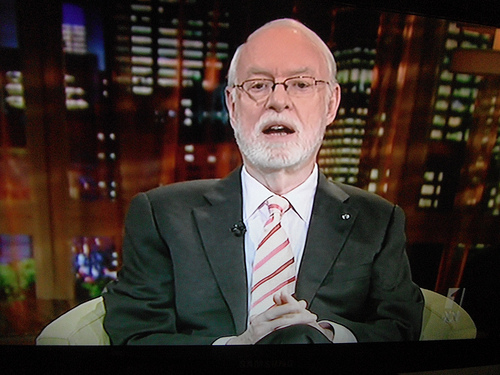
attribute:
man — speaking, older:
[103, 17, 424, 345]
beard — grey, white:
[229, 115, 325, 169]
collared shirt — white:
[239, 163, 318, 330]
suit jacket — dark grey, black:
[100, 163, 424, 344]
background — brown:
[1, 1, 497, 343]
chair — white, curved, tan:
[36, 274, 477, 346]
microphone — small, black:
[230, 217, 248, 237]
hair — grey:
[227, 16, 337, 89]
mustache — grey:
[251, 112, 300, 135]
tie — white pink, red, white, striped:
[249, 195, 295, 328]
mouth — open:
[260, 120, 296, 141]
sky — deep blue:
[2, 1, 105, 71]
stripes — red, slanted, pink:
[250, 203, 297, 319]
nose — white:
[263, 80, 292, 113]